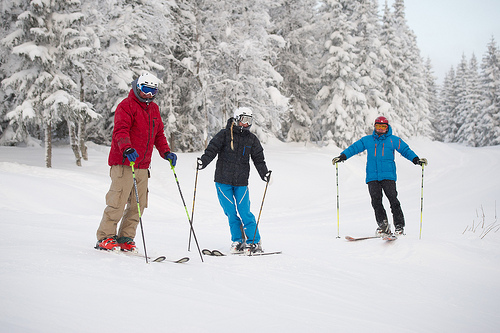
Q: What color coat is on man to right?
A: Blue.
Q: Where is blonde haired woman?
A: One in middle.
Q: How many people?
A: 3.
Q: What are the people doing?
A: Snow skiing.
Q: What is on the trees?
A: Snow.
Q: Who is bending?
A: The man.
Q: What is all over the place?
A: Snow.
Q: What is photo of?
A: 3 skiers.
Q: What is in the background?
A: A group of snow covered pine trees.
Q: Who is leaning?
A: The middle skier.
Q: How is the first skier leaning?
A: Forward.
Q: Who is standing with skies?
A: The skier on the right.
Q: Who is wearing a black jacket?
A: The skier in the middle with skis.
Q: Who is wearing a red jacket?
A: The skier on the left with skis.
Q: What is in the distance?
A: Pine trees covered with snow.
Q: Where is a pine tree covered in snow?
A: Behind the skiers.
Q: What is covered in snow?
A: Trees.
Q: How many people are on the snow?
A: Three.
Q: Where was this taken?
A: Ski slope.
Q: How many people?
A: 3.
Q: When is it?
A: Winter.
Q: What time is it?
A: Day time.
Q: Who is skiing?
A: People.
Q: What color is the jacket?
A: Blue.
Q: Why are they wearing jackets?
A: It cold.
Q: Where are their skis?
A: On the ground.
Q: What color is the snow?
A: White.